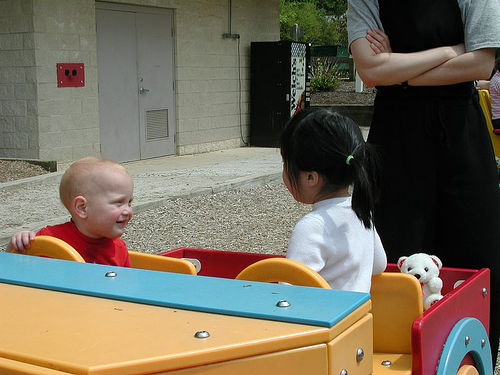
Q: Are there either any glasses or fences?
A: No, there are no fences or glasses.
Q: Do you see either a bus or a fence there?
A: No, there are no fences or buses.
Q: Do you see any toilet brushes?
A: No, there are no toilet brushes.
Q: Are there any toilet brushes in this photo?
A: No, there are no toilet brushes.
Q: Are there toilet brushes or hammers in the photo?
A: No, there are no toilet brushes or hammers.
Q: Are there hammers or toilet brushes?
A: No, there are no toilet brushes or hammers.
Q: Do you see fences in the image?
A: No, there are no fences.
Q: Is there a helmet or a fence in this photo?
A: No, there are no fences or helmets.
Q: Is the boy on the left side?
A: Yes, the boy is on the left of the image.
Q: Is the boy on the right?
A: No, the boy is on the left of the image.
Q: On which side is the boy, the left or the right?
A: The boy is on the left of the image.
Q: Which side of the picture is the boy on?
A: The boy is on the left of the image.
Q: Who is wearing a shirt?
A: The boy is wearing a shirt.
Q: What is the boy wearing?
A: The boy is wearing a shirt.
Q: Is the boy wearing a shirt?
A: Yes, the boy is wearing a shirt.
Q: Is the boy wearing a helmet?
A: No, the boy is wearing a shirt.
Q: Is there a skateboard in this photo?
A: No, there are no skateboards.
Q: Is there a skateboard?
A: No, there are no skateboards.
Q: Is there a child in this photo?
A: Yes, there are children.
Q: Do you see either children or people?
A: Yes, there are children.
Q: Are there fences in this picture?
A: No, there are no fences.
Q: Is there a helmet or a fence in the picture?
A: No, there are no fences or helmets.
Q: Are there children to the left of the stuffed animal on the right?
A: Yes, there are children to the left of the stuffed animal.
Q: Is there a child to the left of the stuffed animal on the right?
A: Yes, there are children to the left of the stuffed animal.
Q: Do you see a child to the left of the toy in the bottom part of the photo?
A: Yes, there are children to the left of the stuffed animal.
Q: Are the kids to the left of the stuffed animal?
A: Yes, the kids are to the left of the stuffed animal.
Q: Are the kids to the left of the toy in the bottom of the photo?
A: Yes, the kids are to the left of the stuffed animal.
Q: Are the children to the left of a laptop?
A: No, the children are to the left of the stuffed animal.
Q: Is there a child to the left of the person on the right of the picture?
A: Yes, there are children to the left of the person.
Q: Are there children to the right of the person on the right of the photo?
A: No, the children are to the left of the person.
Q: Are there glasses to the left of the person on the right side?
A: No, there are children to the left of the person.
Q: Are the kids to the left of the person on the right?
A: Yes, the kids are to the left of the person.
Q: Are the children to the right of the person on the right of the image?
A: No, the children are to the left of the person.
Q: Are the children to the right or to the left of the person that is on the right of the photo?
A: The children are to the left of the person.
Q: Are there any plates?
A: Yes, there is a plate.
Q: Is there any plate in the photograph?
A: Yes, there is a plate.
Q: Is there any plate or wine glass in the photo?
A: Yes, there is a plate.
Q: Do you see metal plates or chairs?
A: Yes, there is a metal plate.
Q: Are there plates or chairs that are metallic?
A: Yes, the plate is metallic.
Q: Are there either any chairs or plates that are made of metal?
A: Yes, the plate is made of metal.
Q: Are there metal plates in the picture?
A: Yes, there is a metal plate.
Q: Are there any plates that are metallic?
A: Yes, there is a plate that is metallic.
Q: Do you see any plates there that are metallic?
A: Yes, there is a plate that is metallic.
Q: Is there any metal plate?
A: Yes, there is a plate that is made of metal.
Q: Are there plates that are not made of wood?
A: Yes, there is a plate that is made of metal.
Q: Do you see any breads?
A: No, there are no breads.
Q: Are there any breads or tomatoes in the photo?
A: No, there are no breads or tomatoes.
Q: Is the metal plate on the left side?
A: Yes, the plate is on the left of the image.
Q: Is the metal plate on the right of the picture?
A: No, the plate is on the left of the image.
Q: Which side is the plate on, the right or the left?
A: The plate is on the left of the image.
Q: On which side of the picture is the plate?
A: The plate is on the left of the image.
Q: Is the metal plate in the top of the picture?
A: Yes, the plate is in the top of the image.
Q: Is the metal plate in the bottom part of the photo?
A: No, the plate is in the top of the image.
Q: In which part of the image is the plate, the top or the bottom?
A: The plate is in the top of the image.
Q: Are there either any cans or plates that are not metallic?
A: No, there is a plate but it is metallic.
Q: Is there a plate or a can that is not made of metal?
A: No, there is a plate but it is made of metal.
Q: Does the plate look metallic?
A: Yes, the plate is metallic.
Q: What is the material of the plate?
A: The plate is made of metal.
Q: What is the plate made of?
A: The plate is made of metal.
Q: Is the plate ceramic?
A: No, the plate is metallic.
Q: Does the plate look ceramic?
A: No, the plate is metallic.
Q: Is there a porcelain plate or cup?
A: No, there is a plate but it is metallic.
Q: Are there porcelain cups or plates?
A: No, there is a plate but it is metallic.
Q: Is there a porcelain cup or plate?
A: No, there is a plate but it is metallic.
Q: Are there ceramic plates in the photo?
A: No, there is a plate but it is metallic.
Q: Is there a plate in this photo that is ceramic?
A: No, there is a plate but it is metallic.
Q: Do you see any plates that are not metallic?
A: No, there is a plate but it is metallic.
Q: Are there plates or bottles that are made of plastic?
A: No, there is a plate but it is made of metal.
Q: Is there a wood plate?
A: No, there is a plate but it is made of metal.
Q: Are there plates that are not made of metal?
A: No, there is a plate but it is made of metal.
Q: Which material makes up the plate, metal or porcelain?
A: The plate is made of metal.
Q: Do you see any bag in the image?
A: No, there are no bags.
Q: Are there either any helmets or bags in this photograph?
A: No, there are no bags or helmets.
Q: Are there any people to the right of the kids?
A: Yes, there is a person to the right of the kids.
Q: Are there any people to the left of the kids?
A: No, the person is to the right of the kids.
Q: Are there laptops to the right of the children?
A: No, there is a person to the right of the children.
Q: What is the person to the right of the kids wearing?
A: The person is wearing a shirt.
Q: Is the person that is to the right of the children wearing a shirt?
A: Yes, the person is wearing a shirt.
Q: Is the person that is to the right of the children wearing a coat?
A: No, the person is wearing a shirt.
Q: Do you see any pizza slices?
A: No, there are no pizza slices.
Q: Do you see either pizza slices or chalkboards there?
A: No, there are no pizza slices or chalkboards.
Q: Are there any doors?
A: Yes, there are doors.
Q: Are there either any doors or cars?
A: Yes, there are doors.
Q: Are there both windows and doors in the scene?
A: No, there are doors but no windows.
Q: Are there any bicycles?
A: No, there are no bicycles.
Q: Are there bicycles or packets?
A: No, there are no bicycles or packets.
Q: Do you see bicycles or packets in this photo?
A: No, there are no bicycles or packets.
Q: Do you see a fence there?
A: No, there are no fences.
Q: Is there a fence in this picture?
A: No, there are no fences.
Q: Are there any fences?
A: No, there are no fences.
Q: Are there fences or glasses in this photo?
A: No, there are no fences or glasses.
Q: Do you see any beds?
A: No, there are no beds.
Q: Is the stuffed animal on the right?
A: Yes, the stuffed animal is on the right of the image.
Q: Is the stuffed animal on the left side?
A: No, the stuffed animal is on the right of the image.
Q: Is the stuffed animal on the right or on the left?
A: The stuffed animal is on the right of the image.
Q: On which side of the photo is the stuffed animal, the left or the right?
A: The stuffed animal is on the right of the image.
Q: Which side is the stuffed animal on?
A: The stuffed animal is on the right of the image.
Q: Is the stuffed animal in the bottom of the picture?
A: Yes, the stuffed animal is in the bottom of the image.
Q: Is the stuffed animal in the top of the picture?
A: No, the stuffed animal is in the bottom of the image.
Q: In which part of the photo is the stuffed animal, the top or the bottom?
A: The stuffed animal is in the bottom of the image.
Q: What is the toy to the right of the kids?
A: The toy is a stuffed animal.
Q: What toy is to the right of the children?
A: The toy is a stuffed animal.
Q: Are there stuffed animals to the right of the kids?
A: Yes, there is a stuffed animal to the right of the kids.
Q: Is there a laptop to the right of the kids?
A: No, there is a stuffed animal to the right of the kids.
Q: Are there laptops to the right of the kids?
A: No, there is a stuffed animal to the right of the kids.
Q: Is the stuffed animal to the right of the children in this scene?
A: Yes, the stuffed animal is to the right of the children.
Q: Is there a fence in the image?
A: No, there are no fences.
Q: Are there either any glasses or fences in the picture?
A: No, there are no fences or glasses.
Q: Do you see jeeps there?
A: No, there are no jeeps.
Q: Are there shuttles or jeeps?
A: No, there are no jeeps or shuttles.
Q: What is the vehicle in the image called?
A: The vehicle is a car.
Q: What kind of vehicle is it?
A: The vehicle is a car.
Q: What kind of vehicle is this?
A: This is a car.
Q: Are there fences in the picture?
A: No, there are no fences.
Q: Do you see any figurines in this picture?
A: No, there are no figurines.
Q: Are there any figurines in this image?
A: No, there are no figurines.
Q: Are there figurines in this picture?
A: No, there are no figurines.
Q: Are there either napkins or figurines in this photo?
A: No, there are no figurines or napkins.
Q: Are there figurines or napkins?
A: No, there are no figurines or napkins.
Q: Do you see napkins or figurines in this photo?
A: No, there are no figurines or napkins.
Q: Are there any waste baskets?
A: No, there are no waste baskets.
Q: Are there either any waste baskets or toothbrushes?
A: No, there are no waste baskets or toothbrushes.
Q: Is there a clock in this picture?
A: No, there are no clocks.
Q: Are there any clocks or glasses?
A: No, there are no clocks or glasses.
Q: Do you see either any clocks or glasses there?
A: No, there are no clocks or glasses.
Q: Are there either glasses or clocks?
A: No, there are no clocks or glasses.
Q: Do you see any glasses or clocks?
A: No, there are no clocks or glasses.